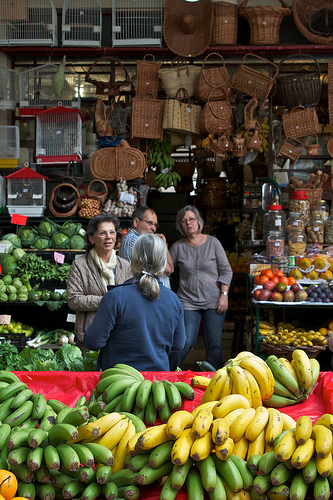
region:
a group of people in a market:
[62, 201, 239, 377]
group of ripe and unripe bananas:
[7, 367, 330, 489]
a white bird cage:
[6, 160, 51, 225]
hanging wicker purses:
[95, 49, 321, 161]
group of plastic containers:
[270, 184, 328, 253]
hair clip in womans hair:
[126, 226, 173, 303]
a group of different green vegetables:
[2, 213, 93, 324]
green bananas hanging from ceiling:
[142, 132, 186, 197]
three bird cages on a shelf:
[2, 1, 174, 54]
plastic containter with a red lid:
[261, 199, 286, 232]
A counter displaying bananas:
[0, 355, 332, 498]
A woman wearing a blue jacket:
[94, 237, 194, 370]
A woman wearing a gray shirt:
[175, 196, 242, 361]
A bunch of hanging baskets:
[88, 59, 331, 182]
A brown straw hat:
[163, 1, 215, 60]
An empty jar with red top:
[257, 198, 285, 242]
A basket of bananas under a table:
[249, 310, 331, 360]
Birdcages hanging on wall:
[1, 91, 80, 220]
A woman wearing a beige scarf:
[69, 213, 134, 299]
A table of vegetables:
[0, 227, 90, 306]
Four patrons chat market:
[65, 198, 246, 371]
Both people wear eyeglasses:
[127, 199, 224, 248]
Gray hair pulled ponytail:
[124, 232, 175, 337]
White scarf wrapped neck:
[69, 221, 130, 294]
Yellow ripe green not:
[88, 352, 332, 496]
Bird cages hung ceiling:
[1, 61, 82, 226]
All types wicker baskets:
[126, 63, 329, 165]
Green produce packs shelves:
[3, 221, 74, 368]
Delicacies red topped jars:
[259, 187, 328, 249]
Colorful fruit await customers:
[253, 256, 332, 352]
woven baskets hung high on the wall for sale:
[130, 0, 332, 148]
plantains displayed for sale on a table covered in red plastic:
[5, 370, 331, 498]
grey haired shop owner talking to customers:
[85, 236, 182, 372]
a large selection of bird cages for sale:
[1, 0, 167, 217]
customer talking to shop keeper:
[63, 215, 134, 360]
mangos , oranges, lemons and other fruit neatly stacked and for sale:
[251, 261, 331, 352]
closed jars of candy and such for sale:
[264, 188, 332, 254]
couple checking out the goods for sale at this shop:
[120, 202, 233, 365]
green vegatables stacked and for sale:
[0, 217, 74, 372]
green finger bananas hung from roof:
[151, 139, 180, 191]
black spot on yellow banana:
[213, 425, 228, 447]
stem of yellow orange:
[0, 468, 26, 492]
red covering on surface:
[39, 369, 89, 387]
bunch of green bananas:
[102, 359, 186, 414]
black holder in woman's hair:
[133, 262, 165, 288]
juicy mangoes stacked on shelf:
[247, 273, 314, 306]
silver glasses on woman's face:
[170, 212, 217, 227]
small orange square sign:
[7, 204, 34, 242]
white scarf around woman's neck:
[86, 249, 128, 284]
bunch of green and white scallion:
[24, 332, 63, 363]